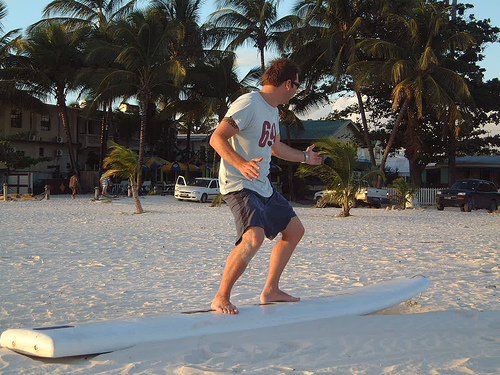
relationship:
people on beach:
[65, 169, 112, 199] [1, 193, 499, 373]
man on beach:
[209, 58, 323, 315] [1, 193, 499, 373]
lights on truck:
[344, 183, 406, 221] [344, 160, 489, 225]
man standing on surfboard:
[209, 55, 325, 315] [47, 315, 294, 360]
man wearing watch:
[209, 58, 323, 315] [299, 147, 312, 167]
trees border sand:
[302, 12, 484, 217] [2, 359, 483, 369]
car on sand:
[435, 179, 499, 213] [1, 195, 498, 373]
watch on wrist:
[301, 151, 309, 164] [301, 145, 309, 164]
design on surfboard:
[31, 322, 72, 335] [13, 277, 415, 359]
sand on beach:
[1, 195, 498, 373] [1, 193, 499, 373]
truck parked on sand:
[311, 176, 404, 208] [19, 208, 499, 368]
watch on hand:
[293, 129, 310, 177] [306, 141, 320, 169]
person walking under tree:
[63, 172, 80, 196] [19, 18, 98, 158]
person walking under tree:
[63, 172, 80, 196] [80, 10, 130, 181]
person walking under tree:
[63, 172, 80, 196] [97, 7, 190, 173]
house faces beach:
[28, 75, 88, 173] [84, 187, 392, 327]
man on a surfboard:
[209, 58, 323, 315] [2, 274, 444, 364]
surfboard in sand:
[123, 295, 336, 345] [413, 284, 485, 324]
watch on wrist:
[301, 151, 309, 164] [301, 143, 308, 172]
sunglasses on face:
[289, 77, 301, 92] [282, 73, 300, 105]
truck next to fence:
[313, 179, 388, 209] [406, 182, 442, 206]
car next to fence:
[438, 176, 498, 216] [406, 182, 442, 206]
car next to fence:
[172, 167, 226, 209] [406, 182, 442, 206]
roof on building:
[8, 84, 93, 137] [0, 75, 178, 197]